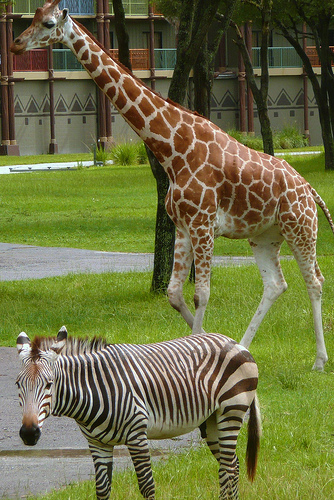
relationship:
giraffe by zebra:
[9, 0, 334, 379] [13, 324, 261, 500]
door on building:
[150, 29, 164, 69] [1, 0, 327, 150]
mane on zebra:
[23, 332, 108, 359] [13, 324, 261, 500]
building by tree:
[1, 0, 327, 150] [208, 0, 291, 159]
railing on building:
[104, 49, 150, 70] [1, 0, 327, 150]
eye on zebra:
[44, 380, 54, 390] [13, 324, 261, 500]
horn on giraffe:
[50, 0, 60, 10] [9, 0, 334, 379]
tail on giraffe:
[306, 183, 333, 227] [9, 0, 334, 379]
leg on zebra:
[126, 434, 160, 499] [13, 324, 261, 500]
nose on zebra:
[19, 427, 45, 439] [13, 324, 261, 500]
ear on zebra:
[52, 324, 70, 358] [13, 324, 261, 500]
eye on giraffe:
[44, 380, 54, 390] [9, 0, 334, 379]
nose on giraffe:
[19, 427, 45, 439] [9, 0, 334, 379]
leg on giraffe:
[126, 434, 160, 499] [9, 0, 334, 379]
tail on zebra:
[306, 183, 333, 227] [13, 324, 261, 500]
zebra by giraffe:
[13, 324, 261, 500] [9, 0, 334, 379]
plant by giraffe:
[80, 136, 117, 165] [9, 0, 334, 379]